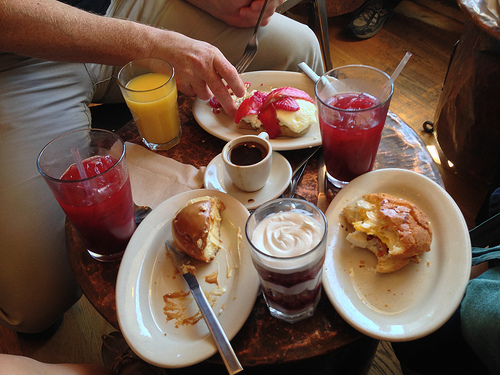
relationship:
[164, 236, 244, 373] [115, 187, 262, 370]
knife on plate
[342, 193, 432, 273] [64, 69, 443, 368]
sandwich on table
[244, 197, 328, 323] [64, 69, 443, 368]
milk shake on table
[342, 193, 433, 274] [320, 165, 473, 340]
sandwich on plate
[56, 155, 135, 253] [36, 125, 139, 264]
juice in glass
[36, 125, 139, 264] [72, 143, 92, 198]
glass with straw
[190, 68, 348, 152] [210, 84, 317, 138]
plate has shortcake